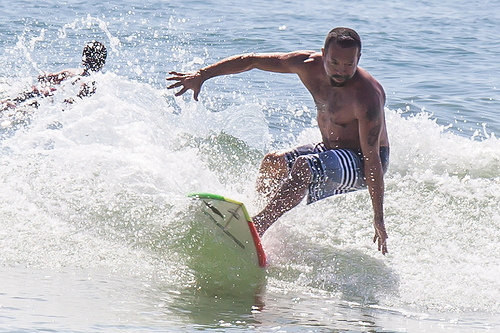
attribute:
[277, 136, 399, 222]
shorts — board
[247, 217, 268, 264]
rim — red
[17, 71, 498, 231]
cap — white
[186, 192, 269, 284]
surfboard — white, blue, green, yellow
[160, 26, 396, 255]
surfer — surfing, wearing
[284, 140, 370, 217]
shorts — black, gray, white, grey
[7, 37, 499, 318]
foam — white, wide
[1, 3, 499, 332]
water — blue, white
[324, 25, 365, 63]
hair — short, dark